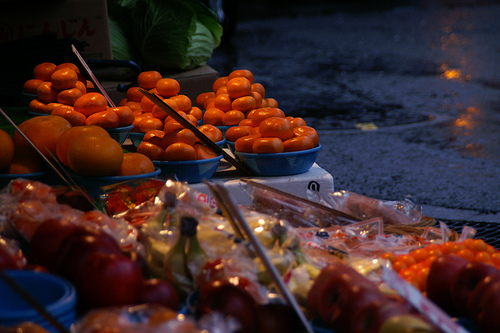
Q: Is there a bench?
A: No, there are no benches.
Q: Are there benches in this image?
A: No, there are no benches.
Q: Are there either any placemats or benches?
A: No, there are no benches or placemats.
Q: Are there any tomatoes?
A: Yes, there is a tomato.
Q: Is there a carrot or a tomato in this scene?
A: Yes, there is a tomato.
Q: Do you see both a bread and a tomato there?
A: No, there is a tomato but no breads.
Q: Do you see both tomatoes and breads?
A: No, there is a tomato but no breads.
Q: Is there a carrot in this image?
A: No, there are no carrots.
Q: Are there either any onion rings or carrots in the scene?
A: No, there are no carrots or onion rings.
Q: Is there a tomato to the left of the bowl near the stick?
A: Yes, there is a tomato to the left of the bowl.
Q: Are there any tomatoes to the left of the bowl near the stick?
A: Yes, there is a tomato to the left of the bowl.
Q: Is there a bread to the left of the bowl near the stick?
A: No, there is a tomato to the left of the bowl.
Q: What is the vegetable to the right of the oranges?
A: The vegetable is a tomato.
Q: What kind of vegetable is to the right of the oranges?
A: The vegetable is a tomato.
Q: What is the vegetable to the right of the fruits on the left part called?
A: The vegetable is a tomato.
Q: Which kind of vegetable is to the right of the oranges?
A: The vegetable is a tomato.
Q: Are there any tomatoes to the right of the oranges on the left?
A: Yes, there is a tomato to the right of the oranges.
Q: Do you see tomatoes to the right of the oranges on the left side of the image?
A: Yes, there is a tomato to the right of the oranges.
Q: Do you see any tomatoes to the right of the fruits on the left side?
A: Yes, there is a tomato to the right of the oranges.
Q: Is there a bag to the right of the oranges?
A: No, there is a tomato to the right of the oranges.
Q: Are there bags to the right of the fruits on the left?
A: No, there is a tomato to the right of the oranges.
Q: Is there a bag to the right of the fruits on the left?
A: No, there is a tomato to the right of the oranges.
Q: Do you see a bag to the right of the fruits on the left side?
A: No, there is a tomato to the right of the oranges.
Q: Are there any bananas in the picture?
A: Yes, there are bananas.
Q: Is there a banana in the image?
A: Yes, there are bananas.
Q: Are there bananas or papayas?
A: Yes, there are bananas.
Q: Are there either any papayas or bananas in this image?
A: Yes, there are bananas.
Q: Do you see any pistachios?
A: No, there are no pistachios.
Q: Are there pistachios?
A: No, there are no pistachios.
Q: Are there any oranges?
A: Yes, there are oranges.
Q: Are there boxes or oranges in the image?
A: Yes, there are oranges.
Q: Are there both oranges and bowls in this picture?
A: Yes, there are both oranges and a bowl.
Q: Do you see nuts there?
A: No, there are no nuts.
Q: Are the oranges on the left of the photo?
A: Yes, the oranges are on the left of the image.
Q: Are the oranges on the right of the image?
A: No, the oranges are on the left of the image.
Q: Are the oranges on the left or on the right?
A: The oranges are on the left of the image.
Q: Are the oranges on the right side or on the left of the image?
A: The oranges are on the left of the image.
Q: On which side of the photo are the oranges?
A: The oranges are on the left of the image.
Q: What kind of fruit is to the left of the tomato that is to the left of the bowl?
A: The fruits are oranges.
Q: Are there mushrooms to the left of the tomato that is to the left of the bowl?
A: No, there are oranges to the left of the tomato.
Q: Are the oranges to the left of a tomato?
A: Yes, the oranges are to the left of a tomato.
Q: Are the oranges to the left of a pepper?
A: No, the oranges are to the left of a tomato.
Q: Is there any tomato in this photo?
A: Yes, there is a tomato.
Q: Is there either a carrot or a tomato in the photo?
A: Yes, there is a tomato.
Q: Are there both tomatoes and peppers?
A: No, there is a tomato but no peppers.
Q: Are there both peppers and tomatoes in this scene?
A: No, there is a tomato but no peppers.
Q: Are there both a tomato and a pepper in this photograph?
A: No, there is a tomato but no peppers.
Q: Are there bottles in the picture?
A: No, there are no bottles.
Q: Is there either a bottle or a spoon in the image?
A: No, there are no bottles or spoons.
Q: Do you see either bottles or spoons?
A: No, there are no bottles or spoons.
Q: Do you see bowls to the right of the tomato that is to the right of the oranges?
A: Yes, there is a bowl to the right of the tomato.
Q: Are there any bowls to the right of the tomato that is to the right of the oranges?
A: Yes, there is a bowl to the right of the tomato.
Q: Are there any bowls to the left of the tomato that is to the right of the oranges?
A: No, the bowl is to the right of the tomato.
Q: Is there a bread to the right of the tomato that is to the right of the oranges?
A: No, there is a bowl to the right of the tomato.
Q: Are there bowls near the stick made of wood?
A: Yes, there is a bowl near the stick.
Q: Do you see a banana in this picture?
A: Yes, there are bananas.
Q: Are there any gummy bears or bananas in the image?
A: Yes, there are bananas.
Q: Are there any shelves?
A: No, there are no shelves.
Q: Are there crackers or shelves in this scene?
A: No, there are no shelves or crackers.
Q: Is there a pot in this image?
A: No, there are no pots.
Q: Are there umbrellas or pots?
A: No, there are no pots or umbrellas.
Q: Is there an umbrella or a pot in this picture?
A: No, there are no pots or umbrellas.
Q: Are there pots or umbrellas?
A: No, there are no pots or umbrellas.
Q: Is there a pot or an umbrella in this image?
A: No, there are no pots or umbrellas.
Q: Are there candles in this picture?
A: No, there are no candles.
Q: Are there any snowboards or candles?
A: No, there are no candles or snowboards.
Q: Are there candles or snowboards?
A: No, there are no candles or snowboards.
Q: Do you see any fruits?
A: Yes, there is a fruit.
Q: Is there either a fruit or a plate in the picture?
A: Yes, there is a fruit.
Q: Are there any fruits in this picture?
A: Yes, there is a fruit.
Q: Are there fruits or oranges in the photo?
A: Yes, there is a fruit.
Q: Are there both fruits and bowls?
A: Yes, there are both a fruit and a bowl.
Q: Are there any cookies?
A: No, there are no cookies.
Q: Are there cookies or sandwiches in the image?
A: No, there are no cookies or sandwiches.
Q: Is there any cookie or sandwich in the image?
A: No, there are no cookies or sandwiches.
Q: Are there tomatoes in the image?
A: Yes, there are tomatoes.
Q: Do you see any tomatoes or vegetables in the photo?
A: Yes, there are tomatoes.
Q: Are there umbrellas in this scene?
A: No, there are no umbrellas.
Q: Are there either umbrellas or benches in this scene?
A: No, there are no umbrellas or benches.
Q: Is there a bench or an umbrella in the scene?
A: No, there are no umbrellas or benches.